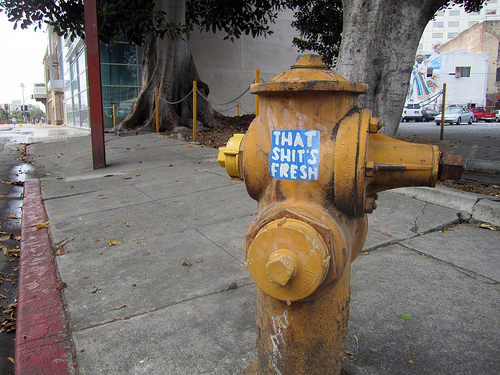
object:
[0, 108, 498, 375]
area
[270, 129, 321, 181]
sign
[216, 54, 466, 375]
fire hydrant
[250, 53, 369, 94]
top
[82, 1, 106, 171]
pole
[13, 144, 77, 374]
edge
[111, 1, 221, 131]
trunk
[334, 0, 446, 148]
trunk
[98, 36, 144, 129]
window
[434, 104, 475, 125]
car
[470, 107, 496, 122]
car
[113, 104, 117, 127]
post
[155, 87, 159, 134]
post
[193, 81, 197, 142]
post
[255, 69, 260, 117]
post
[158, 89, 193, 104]
chain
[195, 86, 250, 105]
chain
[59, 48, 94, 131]
window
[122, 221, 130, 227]
leaf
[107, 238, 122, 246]
leaf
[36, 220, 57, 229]
leaf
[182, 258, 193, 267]
leaf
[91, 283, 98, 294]
leaf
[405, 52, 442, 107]
amusement ride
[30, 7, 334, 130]
building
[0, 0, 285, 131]
tree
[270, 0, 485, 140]
tree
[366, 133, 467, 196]
lot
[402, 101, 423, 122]
van